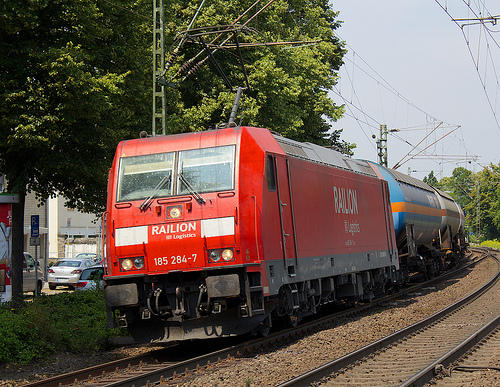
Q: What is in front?
A: A red train engine.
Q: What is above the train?
A: Electricity to the rail cars.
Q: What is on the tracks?
A: Train.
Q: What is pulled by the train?
A: Tank.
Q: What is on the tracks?
A: Tank.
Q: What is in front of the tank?
A: Train.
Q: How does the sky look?
A: Overcast.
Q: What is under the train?
A: Powerlines.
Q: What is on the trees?
A: Green leaves.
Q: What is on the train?
A: Engine.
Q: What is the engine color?
A: Red train.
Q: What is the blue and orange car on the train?
A: Tank.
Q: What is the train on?
A: Tracks.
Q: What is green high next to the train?
A: Tree.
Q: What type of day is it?
A: Overcast.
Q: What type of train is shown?
A: Passenger.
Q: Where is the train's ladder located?
A: On the right side.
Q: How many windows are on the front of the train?
A: Two.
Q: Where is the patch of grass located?
A: Left of the train.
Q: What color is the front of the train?
A: Red.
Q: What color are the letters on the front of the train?
A: White.